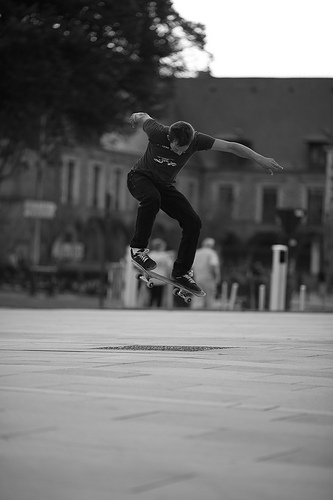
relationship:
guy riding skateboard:
[90, 105, 263, 297] [117, 250, 212, 310]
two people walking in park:
[140, 236, 232, 310] [11, 91, 332, 325]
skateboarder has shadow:
[119, 98, 237, 363] [3, 338, 98, 354]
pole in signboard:
[31, 218, 39, 266] [23, 199, 56, 219]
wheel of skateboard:
[134, 271, 142, 280] [132, 258, 204, 297]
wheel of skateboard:
[147, 280, 154, 289] [132, 258, 204, 297]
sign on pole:
[22, 198, 57, 221] [31, 218, 41, 266]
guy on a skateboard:
[129, 112, 283, 294] [128, 256, 206, 302]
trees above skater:
[0, 0, 214, 177] [125, 109, 284, 296]